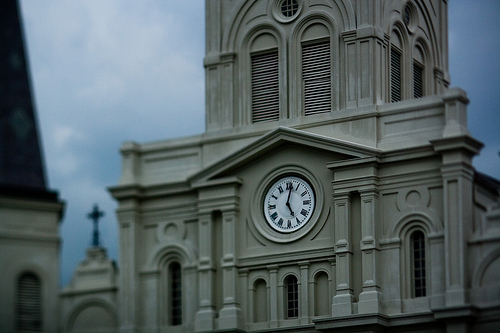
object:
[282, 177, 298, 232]
hands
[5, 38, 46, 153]
shapes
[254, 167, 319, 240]
couple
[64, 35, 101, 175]
sky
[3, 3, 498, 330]
church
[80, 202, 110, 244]
cross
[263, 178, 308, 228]
numerals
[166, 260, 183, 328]
windows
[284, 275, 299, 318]
windows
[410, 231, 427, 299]
windows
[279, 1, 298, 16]
windows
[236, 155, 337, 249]
clock tower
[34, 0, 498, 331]
building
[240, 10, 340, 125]
window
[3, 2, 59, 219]
steeple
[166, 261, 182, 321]
windows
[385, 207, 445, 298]
arches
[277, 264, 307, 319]
arches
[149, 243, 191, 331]
arches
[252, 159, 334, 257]
numbers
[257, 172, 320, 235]
clock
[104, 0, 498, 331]
clocktower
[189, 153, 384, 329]
columns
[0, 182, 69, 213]
roof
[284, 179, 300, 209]
minutes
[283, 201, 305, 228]
five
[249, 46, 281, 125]
blinds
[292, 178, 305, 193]
roman numeral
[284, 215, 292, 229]
roman numeral